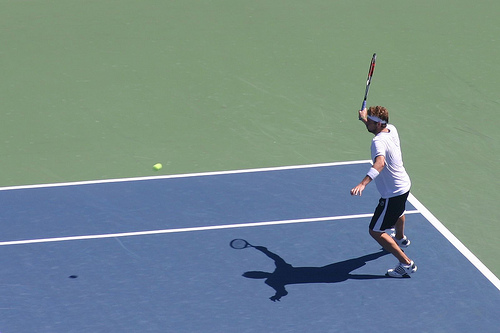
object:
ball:
[152, 164, 161, 170]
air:
[4, 3, 193, 56]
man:
[351, 105, 419, 279]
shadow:
[228, 238, 412, 302]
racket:
[360, 53, 376, 111]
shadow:
[229, 239, 254, 250]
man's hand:
[357, 107, 368, 122]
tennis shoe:
[389, 233, 411, 247]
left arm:
[361, 140, 387, 186]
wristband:
[366, 167, 379, 179]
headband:
[365, 114, 388, 126]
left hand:
[350, 183, 367, 198]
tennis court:
[0, 160, 498, 331]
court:
[0, 0, 500, 333]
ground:
[0, 0, 500, 333]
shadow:
[69, 274, 79, 279]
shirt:
[370, 123, 413, 199]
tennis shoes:
[386, 261, 416, 277]